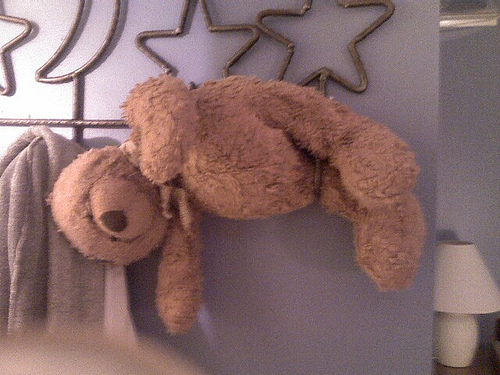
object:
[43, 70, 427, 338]
teddy bear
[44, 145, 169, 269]
head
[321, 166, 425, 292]
leg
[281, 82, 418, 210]
leg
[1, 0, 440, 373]
wall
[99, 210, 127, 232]
nose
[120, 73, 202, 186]
arm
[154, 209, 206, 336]
arm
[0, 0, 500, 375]
room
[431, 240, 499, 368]
lamp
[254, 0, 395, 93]
star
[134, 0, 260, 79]
star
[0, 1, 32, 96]
star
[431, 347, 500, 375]
table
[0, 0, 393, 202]
rod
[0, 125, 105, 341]
cloth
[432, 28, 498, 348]
wall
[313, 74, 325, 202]
hook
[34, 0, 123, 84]
moon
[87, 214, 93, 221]
eye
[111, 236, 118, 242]
eye